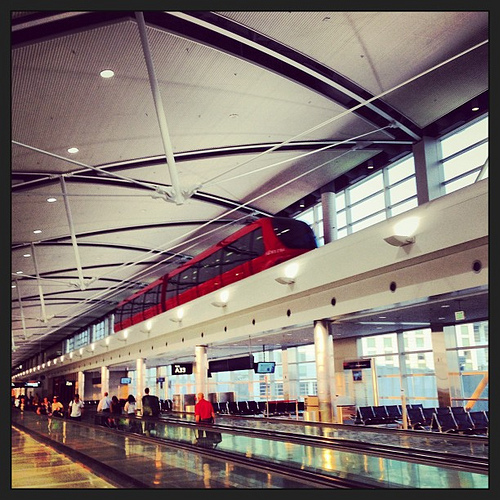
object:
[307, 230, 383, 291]
wall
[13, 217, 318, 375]
carriage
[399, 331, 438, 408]
windows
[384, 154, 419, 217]
window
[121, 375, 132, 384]
tv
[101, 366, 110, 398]
pole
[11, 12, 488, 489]
subway scene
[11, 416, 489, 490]
ground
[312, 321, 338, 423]
pole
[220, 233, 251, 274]
window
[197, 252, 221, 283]
window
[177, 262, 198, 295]
window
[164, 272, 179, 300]
window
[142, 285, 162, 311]
window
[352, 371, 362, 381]
tv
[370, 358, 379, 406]
pole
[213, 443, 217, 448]
belt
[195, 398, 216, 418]
shirt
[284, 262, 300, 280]
lights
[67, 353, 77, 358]
lights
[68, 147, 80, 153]
lights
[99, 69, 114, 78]
lights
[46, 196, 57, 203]
lights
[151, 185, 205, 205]
top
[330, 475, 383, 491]
track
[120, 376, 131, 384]
monitors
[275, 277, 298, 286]
fixture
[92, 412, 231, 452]
conveyer belt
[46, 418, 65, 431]
green grass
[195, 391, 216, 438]
man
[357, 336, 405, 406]
windows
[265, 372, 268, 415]
pole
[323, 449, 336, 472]
shine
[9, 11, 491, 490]
floor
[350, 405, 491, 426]
chairs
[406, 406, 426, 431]
seat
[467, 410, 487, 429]
seat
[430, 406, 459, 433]
seat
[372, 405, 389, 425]
seat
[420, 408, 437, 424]
seat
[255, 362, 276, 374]
monitor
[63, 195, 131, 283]
overhead lighting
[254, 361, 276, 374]
tv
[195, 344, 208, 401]
pole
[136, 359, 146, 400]
pole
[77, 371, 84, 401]
pole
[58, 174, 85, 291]
pole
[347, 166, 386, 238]
windows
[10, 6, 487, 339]
beam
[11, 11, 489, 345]
ceiling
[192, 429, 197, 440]
black bags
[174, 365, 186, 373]
sign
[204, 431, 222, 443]
bag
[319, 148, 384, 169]
trim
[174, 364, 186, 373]
writing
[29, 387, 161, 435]
people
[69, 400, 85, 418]
shirt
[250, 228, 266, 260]
windows